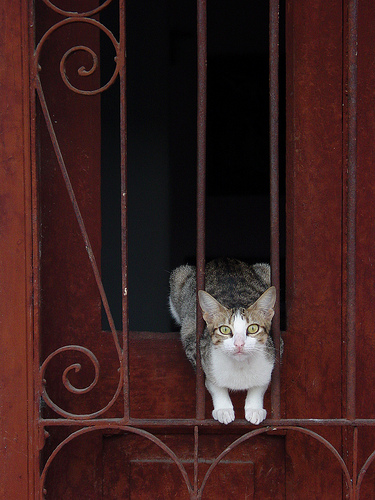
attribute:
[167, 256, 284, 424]
cat — curious, hanging, calico, staring, gray, white, looking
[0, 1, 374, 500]
door — metal, red, iron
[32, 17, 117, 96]
form — spiral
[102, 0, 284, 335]
interior — dark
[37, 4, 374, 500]
wood — varnished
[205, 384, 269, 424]
legs — white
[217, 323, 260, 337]
eyes — yellow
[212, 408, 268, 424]
paws — white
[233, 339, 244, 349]
nose — pink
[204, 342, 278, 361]
whiskers — white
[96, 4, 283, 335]
window — open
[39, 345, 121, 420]
swirl — metal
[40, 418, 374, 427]
rail — brown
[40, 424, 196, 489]
object — brown